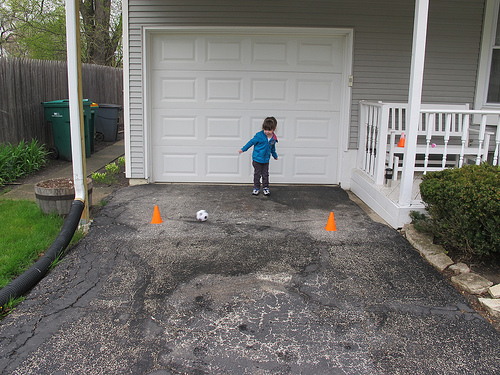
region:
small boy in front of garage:
[247, 113, 276, 190]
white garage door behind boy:
[150, 28, 342, 185]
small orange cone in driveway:
[147, 202, 177, 238]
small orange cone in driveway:
[323, 207, 335, 229]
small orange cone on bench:
[396, 126, 408, 147]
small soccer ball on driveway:
[194, 205, 224, 224]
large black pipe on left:
[11, 218, 106, 313]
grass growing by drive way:
[29, 225, 61, 277]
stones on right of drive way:
[400, 205, 495, 310]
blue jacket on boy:
[246, 122, 271, 161]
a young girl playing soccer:
[135, 105, 340, 259]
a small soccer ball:
[193, 205, 211, 227]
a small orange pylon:
[314, 206, 343, 240]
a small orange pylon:
[139, 200, 166, 227]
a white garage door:
[143, 29, 350, 181]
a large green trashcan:
[41, 91, 98, 159]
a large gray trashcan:
[88, 98, 123, 145]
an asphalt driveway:
[8, 178, 450, 373]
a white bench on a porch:
[372, 95, 493, 176]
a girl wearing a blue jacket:
[233, 105, 293, 199]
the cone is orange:
[322, 208, 339, 242]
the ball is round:
[188, 200, 216, 229]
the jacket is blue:
[237, 130, 280, 164]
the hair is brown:
[264, 119, 277, 130]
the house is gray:
[357, 36, 409, 92]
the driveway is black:
[122, 269, 356, 357]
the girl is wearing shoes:
[248, 185, 275, 201]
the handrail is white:
[433, 111, 496, 160]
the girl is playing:
[232, 102, 292, 196]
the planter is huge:
[29, 172, 74, 218]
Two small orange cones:
[143, 198, 347, 246]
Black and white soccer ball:
[189, 204, 214, 226]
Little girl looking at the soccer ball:
[238, 113, 288, 204]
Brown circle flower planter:
[30, 164, 92, 229]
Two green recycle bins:
[32, 91, 107, 174]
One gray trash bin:
[90, 96, 129, 154]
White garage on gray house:
[136, 16, 360, 198]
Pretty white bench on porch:
[381, 96, 493, 187]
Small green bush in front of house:
[410, 156, 499, 267]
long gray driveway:
[0, 176, 499, 373]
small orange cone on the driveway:
[322, 206, 342, 236]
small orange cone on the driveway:
[148, 200, 168, 228]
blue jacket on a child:
[243, 125, 283, 166]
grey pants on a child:
[250, 159, 271, 186]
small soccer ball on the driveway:
[193, 205, 214, 228]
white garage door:
[136, 31, 349, 187]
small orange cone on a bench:
[393, 133, 408, 148]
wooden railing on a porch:
[358, 96, 493, 192]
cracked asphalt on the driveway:
[67, 262, 103, 346]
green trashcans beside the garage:
[45, 89, 99, 163]